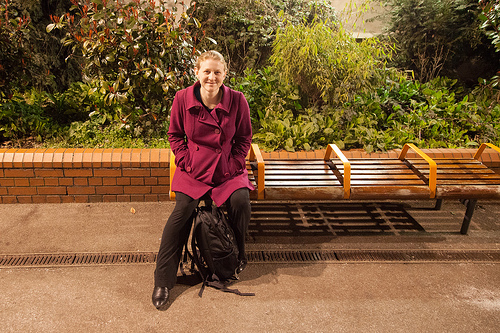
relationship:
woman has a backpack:
[133, 34, 263, 307] [189, 205, 252, 300]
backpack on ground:
[189, 205, 252, 300] [3, 201, 497, 332]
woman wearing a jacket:
[133, 34, 263, 307] [166, 91, 259, 202]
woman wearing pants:
[133, 34, 263, 307] [156, 189, 251, 280]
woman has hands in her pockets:
[133, 34, 263, 307] [181, 157, 241, 185]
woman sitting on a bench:
[133, 34, 263, 307] [166, 144, 499, 207]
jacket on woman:
[166, 91, 259, 202] [133, 34, 263, 307]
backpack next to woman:
[189, 205, 252, 300] [133, 34, 263, 307]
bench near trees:
[166, 144, 499, 207] [2, 3, 499, 155]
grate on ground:
[252, 242, 331, 268] [3, 201, 497, 332]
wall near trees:
[4, 151, 498, 203] [2, 3, 499, 155]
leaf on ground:
[131, 207, 136, 216] [3, 201, 497, 332]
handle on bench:
[250, 139, 269, 191] [166, 144, 499, 207]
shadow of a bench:
[215, 198, 428, 250] [166, 144, 499, 207]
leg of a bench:
[457, 205, 479, 237] [166, 144, 499, 207]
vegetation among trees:
[4, 88, 496, 151] [2, 3, 499, 155]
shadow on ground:
[215, 198, 428, 250] [3, 201, 497, 332]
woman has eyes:
[133, 34, 263, 307] [204, 71, 223, 77]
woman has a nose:
[133, 34, 263, 307] [209, 72, 217, 83]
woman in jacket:
[133, 34, 263, 307] [166, 91, 259, 202]